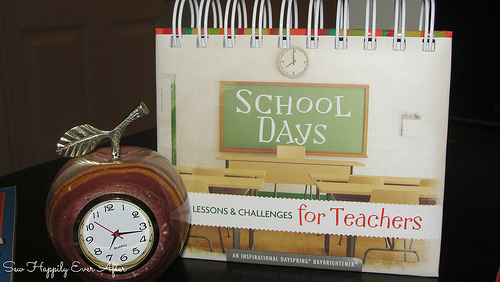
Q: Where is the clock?
A: On the desk.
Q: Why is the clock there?
A: To show time.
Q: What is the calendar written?
A: School days.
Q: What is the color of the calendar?
A: White.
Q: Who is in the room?
A: No one.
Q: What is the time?
A: 7:16.